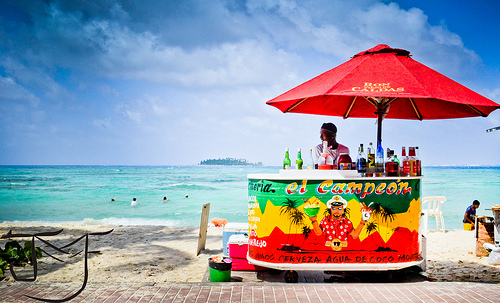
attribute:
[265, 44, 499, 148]
umbrella — red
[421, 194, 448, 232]
chair — plastic, white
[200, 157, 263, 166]
island — distant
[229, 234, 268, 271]
cooler — red, white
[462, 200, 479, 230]
man — eating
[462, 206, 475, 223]
shirt — blue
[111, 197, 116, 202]
swimmer — swimming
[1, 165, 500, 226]
water — brilliant blue, tropical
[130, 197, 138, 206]
swimmer — swimming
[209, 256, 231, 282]
trash can — green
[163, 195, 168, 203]
swimmer — swimming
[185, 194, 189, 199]
swimmer — swimming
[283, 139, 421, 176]
bottles — lined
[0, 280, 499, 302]
walkway — bricks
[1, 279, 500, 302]
bricks — red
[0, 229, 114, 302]
jf — black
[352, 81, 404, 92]
writing — yellow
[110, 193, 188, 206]
people — swimming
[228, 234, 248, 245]
lid — white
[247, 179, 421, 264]
design — yellow, re, green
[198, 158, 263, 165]
trees — distant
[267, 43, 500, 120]
umbrella — red